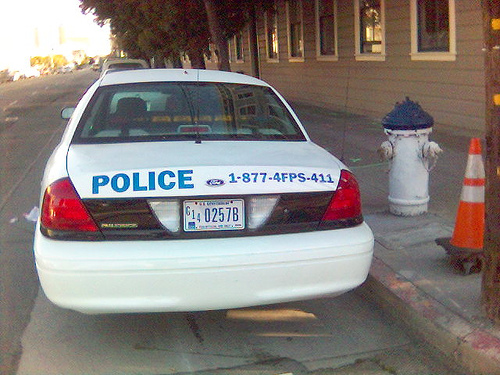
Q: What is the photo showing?
A: It is showing a sidewalk.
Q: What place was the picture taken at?
A: It was taken at the sidewalk.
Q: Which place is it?
A: It is a sidewalk.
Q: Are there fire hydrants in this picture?
A: Yes, there is a fire hydrant.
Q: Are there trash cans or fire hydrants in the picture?
A: Yes, there is a fire hydrant.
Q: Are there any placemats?
A: No, there are no placemats.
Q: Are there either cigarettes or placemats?
A: No, there are no placemats or cigarettes.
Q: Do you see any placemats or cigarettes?
A: No, there are no placemats or cigarettes.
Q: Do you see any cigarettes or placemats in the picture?
A: No, there are no placemats or cigarettes.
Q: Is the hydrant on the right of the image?
A: Yes, the hydrant is on the right of the image.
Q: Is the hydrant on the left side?
A: No, the hydrant is on the right of the image.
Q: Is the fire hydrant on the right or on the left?
A: The fire hydrant is on the right of the image.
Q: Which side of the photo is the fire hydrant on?
A: The fire hydrant is on the right of the image.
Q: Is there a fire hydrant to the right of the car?
A: Yes, there is a fire hydrant to the right of the car.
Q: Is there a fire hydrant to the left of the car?
A: No, the fire hydrant is to the right of the car.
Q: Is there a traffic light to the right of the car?
A: No, there is a fire hydrant to the right of the car.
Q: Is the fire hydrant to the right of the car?
A: Yes, the fire hydrant is to the right of the car.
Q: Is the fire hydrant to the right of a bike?
A: No, the fire hydrant is to the right of the car.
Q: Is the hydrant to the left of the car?
A: No, the hydrant is to the right of the car.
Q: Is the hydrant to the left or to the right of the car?
A: The hydrant is to the right of the car.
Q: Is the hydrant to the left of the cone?
A: Yes, the hydrant is to the left of the cone.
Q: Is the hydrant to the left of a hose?
A: No, the hydrant is to the left of the cone.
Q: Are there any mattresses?
A: No, there are no mattresses.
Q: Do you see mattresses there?
A: No, there are no mattresses.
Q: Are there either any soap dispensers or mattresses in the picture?
A: No, there are no mattresses or soap dispensers.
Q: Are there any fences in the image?
A: No, there are no fences.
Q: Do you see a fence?
A: No, there are no fences.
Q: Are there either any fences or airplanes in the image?
A: No, there are no fences or airplanes.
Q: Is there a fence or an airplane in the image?
A: No, there are no fences or airplanes.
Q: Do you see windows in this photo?
A: Yes, there are windows.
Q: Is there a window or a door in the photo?
A: Yes, there are windows.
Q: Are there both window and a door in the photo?
A: No, there are windows but no doors.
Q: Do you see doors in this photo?
A: No, there are no doors.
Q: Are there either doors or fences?
A: No, there are no doors or fences.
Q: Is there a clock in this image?
A: No, there are no clocks.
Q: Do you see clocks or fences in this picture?
A: No, there are no clocks or fences.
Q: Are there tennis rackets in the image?
A: No, there are no tennis rackets.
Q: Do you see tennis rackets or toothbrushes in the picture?
A: No, there are no tennis rackets or toothbrushes.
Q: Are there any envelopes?
A: No, there are no envelopes.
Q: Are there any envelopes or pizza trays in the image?
A: No, there are no envelopes or pizza trays.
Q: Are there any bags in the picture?
A: No, there are no bags.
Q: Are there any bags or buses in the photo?
A: No, there are no bags or buses.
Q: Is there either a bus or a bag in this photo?
A: No, there are no bags or buses.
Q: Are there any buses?
A: No, there are no buses.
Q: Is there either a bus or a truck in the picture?
A: No, there are no buses or trucks.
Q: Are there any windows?
A: Yes, there is a window.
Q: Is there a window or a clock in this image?
A: Yes, there is a window.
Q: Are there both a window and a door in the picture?
A: No, there is a window but no doors.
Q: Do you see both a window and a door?
A: No, there is a window but no doors.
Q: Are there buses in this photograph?
A: No, there are no buses.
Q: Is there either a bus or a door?
A: No, there are no buses or doors.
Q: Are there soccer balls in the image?
A: No, there are no soccer balls.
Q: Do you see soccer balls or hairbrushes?
A: No, there are no soccer balls or hairbrushes.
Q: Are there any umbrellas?
A: No, there are no umbrellas.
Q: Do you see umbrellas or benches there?
A: No, there are no umbrellas or benches.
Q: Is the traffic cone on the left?
A: No, the traffic cone is on the right of the image.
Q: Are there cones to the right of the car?
A: Yes, there is a cone to the right of the car.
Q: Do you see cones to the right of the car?
A: Yes, there is a cone to the right of the car.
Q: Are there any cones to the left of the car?
A: No, the cone is to the right of the car.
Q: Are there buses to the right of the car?
A: No, there is a cone to the right of the car.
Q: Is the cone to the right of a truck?
A: No, the cone is to the right of a car.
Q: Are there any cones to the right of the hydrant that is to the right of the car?
A: Yes, there is a cone to the right of the fire hydrant.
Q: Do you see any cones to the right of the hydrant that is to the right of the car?
A: Yes, there is a cone to the right of the fire hydrant.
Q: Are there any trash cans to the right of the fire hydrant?
A: No, there is a cone to the right of the fire hydrant.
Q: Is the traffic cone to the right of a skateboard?
A: No, the traffic cone is to the right of the fire hydrant.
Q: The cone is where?
A: The cone is on the sidewalk.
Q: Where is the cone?
A: The cone is on the sidewalk.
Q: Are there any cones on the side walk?
A: Yes, there is a cone on the side walk.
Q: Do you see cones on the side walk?
A: Yes, there is a cone on the side walk.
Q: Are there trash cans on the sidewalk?
A: No, there is a cone on the sidewalk.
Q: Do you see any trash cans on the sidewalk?
A: No, there is a cone on the sidewalk.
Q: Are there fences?
A: No, there are no fences.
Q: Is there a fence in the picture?
A: No, there are no fences.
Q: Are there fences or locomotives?
A: No, there are no fences or locomotives.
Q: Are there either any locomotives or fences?
A: No, there are no fences or locomotives.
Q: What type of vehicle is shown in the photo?
A: The vehicle is a car.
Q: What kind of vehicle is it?
A: The vehicle is a car.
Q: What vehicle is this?
A: This is a car.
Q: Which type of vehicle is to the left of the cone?
A: The vehicle is a car.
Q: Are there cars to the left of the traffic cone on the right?
A: Yes, there is a car to the left of the traffic cone.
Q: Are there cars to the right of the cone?
A: No, the car is to the left of the cone.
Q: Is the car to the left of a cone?
A: Yes, the car is to the left of a cone.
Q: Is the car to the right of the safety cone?
A: No, the car is to the left of the safety cone.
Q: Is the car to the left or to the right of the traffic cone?
A: The car is to the left of the traffic cone.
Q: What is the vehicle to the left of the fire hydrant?
A: The vehicle is a car.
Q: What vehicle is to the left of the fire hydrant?
A: The vehicle is a car.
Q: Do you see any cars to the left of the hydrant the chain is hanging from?
A: Yes, there is a car to the left of the hydrant.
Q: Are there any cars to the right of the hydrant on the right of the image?
A: No, the car is to the left of the fire hydrant.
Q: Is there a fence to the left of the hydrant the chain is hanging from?
A: No, there is a car to the left of the fire hydrant.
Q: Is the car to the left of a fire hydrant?
A: Yes, the car is to the left of a fire hydrant.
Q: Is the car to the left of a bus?
A: No, the car is to the left of a fire hydrant.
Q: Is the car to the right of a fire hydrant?
A: No, the car is to the left of a fire hydrant.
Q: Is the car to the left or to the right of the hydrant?
A: The car is to the left of the hydrant.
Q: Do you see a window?
A: Yes, there is a window.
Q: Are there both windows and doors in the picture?
A: No, there is a window but no doors.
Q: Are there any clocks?
A: No, there are no clocks.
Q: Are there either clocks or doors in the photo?
A: No, there are no clocks or doors.